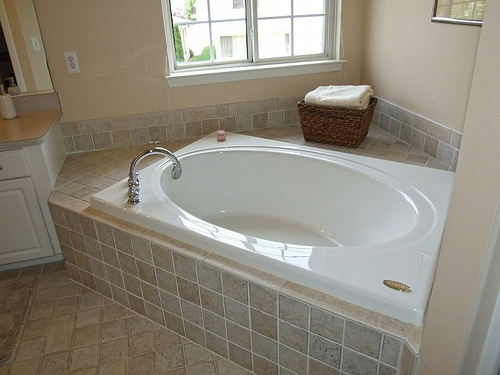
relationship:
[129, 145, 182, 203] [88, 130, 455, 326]
faucet for bathtub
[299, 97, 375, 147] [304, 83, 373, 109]
basket of towel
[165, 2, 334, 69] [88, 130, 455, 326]
window next to bathtub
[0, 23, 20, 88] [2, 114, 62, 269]
mirror on top of dresser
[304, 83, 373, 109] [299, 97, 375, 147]
towel in basket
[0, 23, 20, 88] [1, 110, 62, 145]
mirror over counter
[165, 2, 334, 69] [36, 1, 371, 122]
window against wall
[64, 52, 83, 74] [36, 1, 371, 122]
electrical socket on wall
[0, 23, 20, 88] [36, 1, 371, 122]
mirror on wall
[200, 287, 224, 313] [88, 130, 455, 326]
tile lining bathtub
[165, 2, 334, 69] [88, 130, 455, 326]
window over bathtub